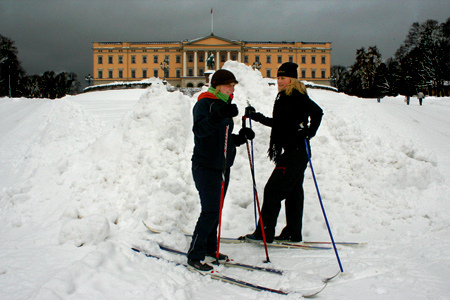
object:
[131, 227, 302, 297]
ski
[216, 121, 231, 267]
pole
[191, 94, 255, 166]
black outfits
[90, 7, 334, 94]
building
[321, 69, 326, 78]
windows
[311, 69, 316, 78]
windows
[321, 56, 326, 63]
windows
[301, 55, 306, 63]
windows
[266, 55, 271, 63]
windows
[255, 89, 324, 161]
sweater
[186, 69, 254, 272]
girl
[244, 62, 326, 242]
girl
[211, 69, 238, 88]
cap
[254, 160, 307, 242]
black pants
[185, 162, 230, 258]
black pants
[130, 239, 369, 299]
skis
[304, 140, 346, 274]
pole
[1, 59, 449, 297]
snow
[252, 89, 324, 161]
jacket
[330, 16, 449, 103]
trees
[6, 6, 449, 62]
sky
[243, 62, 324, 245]
female skier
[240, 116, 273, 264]
pole